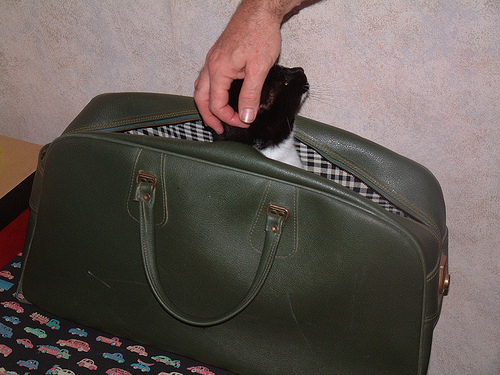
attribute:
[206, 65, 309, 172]
kitten — white, black, stroked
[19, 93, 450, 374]
bag — green, open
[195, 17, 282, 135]
hand — petting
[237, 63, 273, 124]
thumb — here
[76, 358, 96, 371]
car — colorful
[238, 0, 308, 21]
arm — hairy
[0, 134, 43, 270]
box — black, white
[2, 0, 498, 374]
wall — gray, covered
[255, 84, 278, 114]
eyes — closed